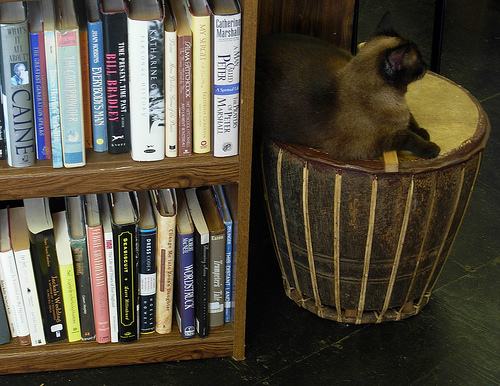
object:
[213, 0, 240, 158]
books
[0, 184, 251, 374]
shelf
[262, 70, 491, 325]
drum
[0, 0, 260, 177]
bookcase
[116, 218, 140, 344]
spine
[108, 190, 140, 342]
book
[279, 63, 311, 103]
fur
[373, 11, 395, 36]
ear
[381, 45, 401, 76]
ear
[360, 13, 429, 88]
head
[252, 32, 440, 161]
cat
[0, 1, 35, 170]
books